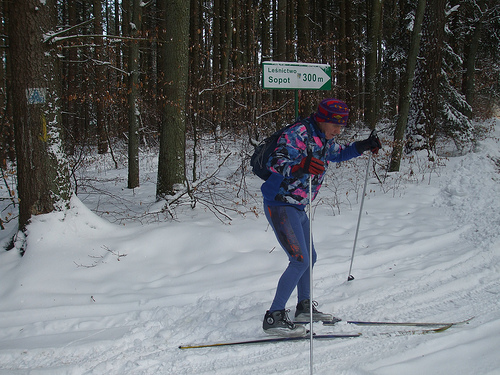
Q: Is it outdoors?
A: Yes, it is outdoors.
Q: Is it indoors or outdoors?
A: It is outdoors.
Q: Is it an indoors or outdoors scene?
A: It is outdoors.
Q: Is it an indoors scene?
A: No, it is outdoors.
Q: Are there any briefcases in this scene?
A: No, there are no briefcases.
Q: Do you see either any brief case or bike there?
A: No, there are no briefcases or bikes.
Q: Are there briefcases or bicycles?
A: No, there are no briefcases or bicycles.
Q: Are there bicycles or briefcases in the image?
A: No, there are no briefcases or bicycles.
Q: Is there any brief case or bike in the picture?
A: No, there are no briefcases or bikes.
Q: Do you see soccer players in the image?
A: No, there are no soccer players.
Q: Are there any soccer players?
A: No, there are no soccer players.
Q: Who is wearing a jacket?
A: The man is wearing a jacket.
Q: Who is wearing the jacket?
A: The man is wearing a jacket.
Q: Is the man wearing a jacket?
A: Yes, the man is wearing a jacket.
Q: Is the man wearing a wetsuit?
A: No, the man is wearing a jacket.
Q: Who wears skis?
A: The man wears skis.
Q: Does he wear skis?
A: Yes, the man wears skis.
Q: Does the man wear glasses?
A: No, the man wears skis.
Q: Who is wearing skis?
A: The man is wearing skis.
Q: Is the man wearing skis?
A: Yes, the man is wearing skis.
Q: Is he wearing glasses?
A: No, the man is wearing skis.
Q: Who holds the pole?
A: The man holds the pole.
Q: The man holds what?
A: The man holds the pole.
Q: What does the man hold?
A: The man holds the pole.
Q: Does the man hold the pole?
A: Yes, the man holds the pole.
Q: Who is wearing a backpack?
A: The man is wearing a backpack.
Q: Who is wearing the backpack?
A: The man is wearing a backpack.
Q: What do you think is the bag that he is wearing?
A: The bag is a backpack.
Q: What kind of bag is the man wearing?
A: The man is wearing a backpack.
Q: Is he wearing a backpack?
A: Yes, the man is wearing a backpack.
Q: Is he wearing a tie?
A: No, the man is wearing a backpack.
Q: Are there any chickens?
A: No, there are no chickens.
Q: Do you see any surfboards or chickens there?
A: No, there are no chickens or surfboards.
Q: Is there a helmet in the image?
A: No, there are no helmets.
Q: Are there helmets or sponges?
A: No, there are no helmets or sponges.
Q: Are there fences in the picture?
A: No, there are no fences.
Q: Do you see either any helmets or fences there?
A: No, there are no fences or helmets.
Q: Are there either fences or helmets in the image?
A: No, there are no fences or helmets.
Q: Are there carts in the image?
A: No, there are no carts.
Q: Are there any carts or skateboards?
A: No, there are no carts or skateboards.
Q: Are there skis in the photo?
A: Yes, there are skis.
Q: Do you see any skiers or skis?
A: Yes, there are skis.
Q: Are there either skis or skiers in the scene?
A: Yes, there are skis.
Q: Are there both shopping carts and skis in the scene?
A: No, there are skis but no shopping carts.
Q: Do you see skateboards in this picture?
A: No, there are no skateboards.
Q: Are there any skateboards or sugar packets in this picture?
A: No, there are no skateboards or sugar packets.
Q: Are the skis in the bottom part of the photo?
A: Yes, the skis are in the bottom of the image.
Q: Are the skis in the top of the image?
A: No, the skis are in the bottom of the image.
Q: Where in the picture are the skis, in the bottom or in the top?
A: The skis are in the bottom of the image.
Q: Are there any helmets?
A: No, there are no helmets.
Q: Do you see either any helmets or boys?
A: No, there are no helmets or boys.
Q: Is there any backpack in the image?
A: Yes, there is a backpack.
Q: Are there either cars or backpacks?
A: Yes, there is a backpack.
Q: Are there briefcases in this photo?
A: No, there are no briefcases.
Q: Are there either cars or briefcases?
A: No, there are no briefcases or cars.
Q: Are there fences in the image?
A: No, there are no fences.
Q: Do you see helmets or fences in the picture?
A: No, there are no fences or helmets.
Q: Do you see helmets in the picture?
A: No, there are no helmets.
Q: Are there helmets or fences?
A: No, there are no helmets or fences.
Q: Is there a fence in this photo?
A: No, there are no fences.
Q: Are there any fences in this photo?
A: No, there are no fences.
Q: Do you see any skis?
A: Yes, there are skis.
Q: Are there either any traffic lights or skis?
A: Yes, there are skis.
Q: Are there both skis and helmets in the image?
A: No, there are skis but no helmets.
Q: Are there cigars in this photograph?
A: No, there are no cigars.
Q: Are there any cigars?
A: No, there are no cigars.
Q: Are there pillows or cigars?
A: No, there are no cigars or pillows.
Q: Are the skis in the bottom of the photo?
A: Yes, the skis are in the bottom of the image.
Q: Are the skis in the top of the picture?
A: No, the skis are in the bottom of the image.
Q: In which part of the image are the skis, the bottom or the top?
A: The skis are in the bottom of the image.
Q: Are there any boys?
A: No, there are no boys.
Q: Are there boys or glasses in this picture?
A: No, there are no boys or glasses.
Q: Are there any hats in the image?
A: Yes, there is a hat.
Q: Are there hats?
A: Yes, there is a hat.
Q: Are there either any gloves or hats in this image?
A: Yes, there is a hat.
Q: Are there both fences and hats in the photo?
A: No, there is a hat but no fences.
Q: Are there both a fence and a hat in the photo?
A: No, there is a hat but no fences.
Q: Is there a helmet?
A: No, there are no helmets.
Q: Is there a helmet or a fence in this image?
A: No, there are no helmets or fences.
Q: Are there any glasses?
A: No, there are no glasses.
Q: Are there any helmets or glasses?
A: No, there are no glasses or helmets.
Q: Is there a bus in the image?
A: No, there are no buses.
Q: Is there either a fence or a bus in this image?
A: No, there are no buses or fences.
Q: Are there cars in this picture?
A: No, there are no cars.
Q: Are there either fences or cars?
A: No, there are no cars or fences.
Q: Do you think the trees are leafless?
A: Yes, the trees are leafless.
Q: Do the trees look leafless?
A: Yes, the trees are leafless.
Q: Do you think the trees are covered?
A: No, the trees are leafless.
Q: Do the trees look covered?
A: No, the trees are leafless.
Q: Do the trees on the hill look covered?
A: No, the trees are leafless.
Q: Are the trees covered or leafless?
A: The trees are leafless.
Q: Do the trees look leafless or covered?
A: The trees are leafless.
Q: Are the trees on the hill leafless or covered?
A: The trees are leafless.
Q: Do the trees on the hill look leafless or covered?
A: The trees are leafless.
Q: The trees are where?
A: The trees are on the hill.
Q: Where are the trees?
A: The trees are on the hill.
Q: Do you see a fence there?
A: No, there are no fences.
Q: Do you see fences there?
A: No, there are no fences.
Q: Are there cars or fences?
A: No, there are no fences or cars.